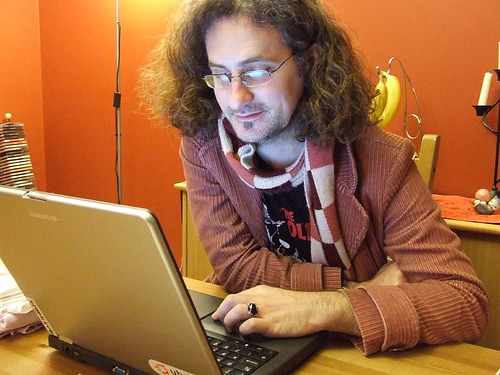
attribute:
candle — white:
[477, 71, 492, 109]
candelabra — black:
[467, 63, 497, 145]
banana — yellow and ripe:
[368, 70, 413, 117]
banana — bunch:
[386, 94, 406, 118]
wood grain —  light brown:
[1, 276, 497, 373]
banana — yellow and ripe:
[387, 90, 402, 124]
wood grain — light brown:
[318, 356, 495, 373]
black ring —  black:
[248, 300, 258, 319]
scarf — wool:
[197, 109, 385, 254]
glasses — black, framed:
[200, 50, 300, 90]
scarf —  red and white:
[235, 152, 353, 249]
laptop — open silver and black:
[3, 174, 335, 374]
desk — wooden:
[0, 230, 499, 375]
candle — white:
[450, 55, 498, 142]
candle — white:
[475, 69, 491, 104]